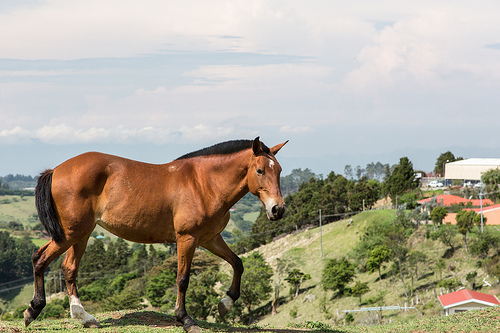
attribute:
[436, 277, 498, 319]
roof — red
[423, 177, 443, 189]
truck — white, parked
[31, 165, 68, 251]
tail — black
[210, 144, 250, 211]
neck — of  horse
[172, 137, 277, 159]
black hair —  Black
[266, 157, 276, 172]
spot — white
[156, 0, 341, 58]
sky — cloudy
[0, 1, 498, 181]
sky —  blue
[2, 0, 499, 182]
clouds —  white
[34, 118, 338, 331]
horse — brown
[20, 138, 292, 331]
horse —  brown, brown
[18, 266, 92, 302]
poles —  for Power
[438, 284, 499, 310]
roof — red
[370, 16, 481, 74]
clouds —  white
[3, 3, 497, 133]
sky —  blue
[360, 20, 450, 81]
clouds —  white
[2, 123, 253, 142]
clouds —  in distance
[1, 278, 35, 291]
lines —  for Power